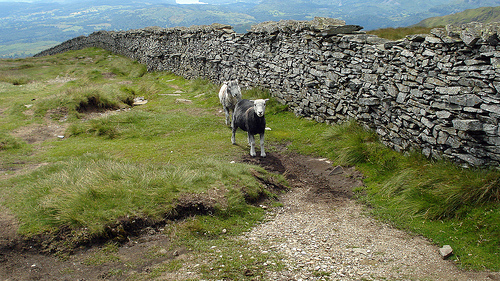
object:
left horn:
[264, 98, 270, 101]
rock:
[436, 110, 452, 119]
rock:
[396, 92, 408, 104]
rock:
[422, 50, 435, 57]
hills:
[3, 0, 500, 16]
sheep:
[219, 79, 271, 158]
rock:
[440, 245, 454, 260]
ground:
[176, 167, 403, 252]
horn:
[250, 99, 256, 102]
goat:
[231, 98, 271, 157]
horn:
[223, 81, 227, 84]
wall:
[293, 27, 499, 147]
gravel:
[235, 183, 426, 279]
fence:
[32, 17, 499, 168]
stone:
[199, 56, 206, 61]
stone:
[174, 54, 181, 57]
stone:
[183, 33, 196, 38]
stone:
[215, 54, 223, 59]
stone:
[205, 44, 210, 47]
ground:
[296, 186, 363, 246]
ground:
[269, 203, 426, 280]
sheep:
[215, 75, 245, 127]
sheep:
[220, 100, 290, 158]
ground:
[394, 110, 469, 162]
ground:
[248, 136, 355, 278]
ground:
[0, 46, 499, 279]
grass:
[363, 26, 443, 40]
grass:
[0, 60, 498, 236]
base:
[24, 93, 474, 209]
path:
[204, 145, 497, 279]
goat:
[218, 79, 242, 125]